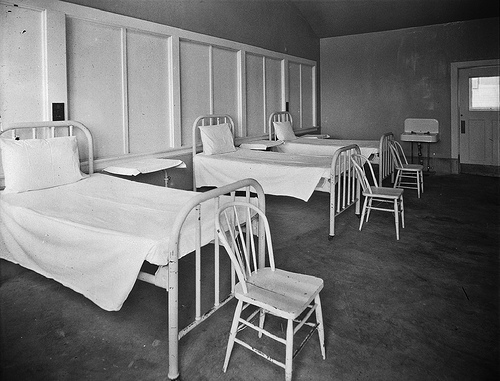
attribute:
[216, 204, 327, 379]
chair — white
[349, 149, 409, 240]
chair — white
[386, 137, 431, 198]
chair — white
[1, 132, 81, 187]
pillow — white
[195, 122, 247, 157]
pillow — white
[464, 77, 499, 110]
window — clear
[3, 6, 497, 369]
photo — black, white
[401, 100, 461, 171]
sink — white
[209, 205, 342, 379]
chair — wooden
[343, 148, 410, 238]
chair — wooden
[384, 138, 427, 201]
chair — wooden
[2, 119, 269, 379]
bed — standard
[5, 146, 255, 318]
linens — white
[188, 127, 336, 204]
linens — white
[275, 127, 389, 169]
linens — white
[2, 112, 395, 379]
bed frames — metal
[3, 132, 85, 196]
pillow — white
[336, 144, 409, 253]
chair — white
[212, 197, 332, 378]
chair — white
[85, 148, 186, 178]
cloth — white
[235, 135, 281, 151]
cloth — white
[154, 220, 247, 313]
frame — metal